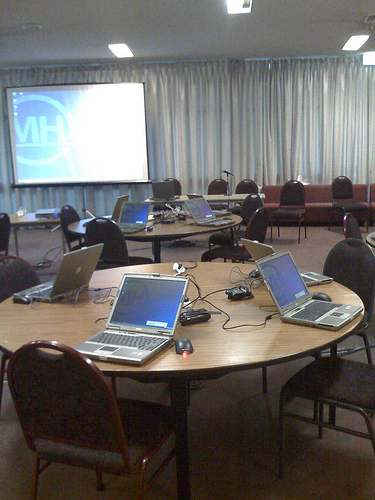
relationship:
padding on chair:
[42, 351, 123, 456] [28, 331, 156, 477]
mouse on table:
[177, 294, 251, 346] [43, 278, 230, 372]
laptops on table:
[49, 232, 257, 328] [43, 278, 230, 372]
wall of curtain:
[40, 74, 369, 217] [165, 86, 204, 170]